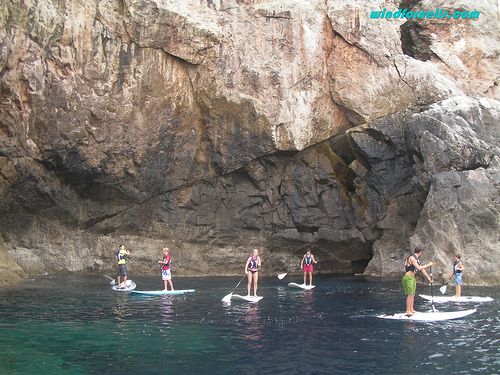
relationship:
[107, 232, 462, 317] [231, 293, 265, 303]
people on paddle board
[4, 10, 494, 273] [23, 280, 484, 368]
cliff above water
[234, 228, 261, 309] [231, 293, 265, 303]
girl on paddle board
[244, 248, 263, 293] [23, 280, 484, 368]
person in water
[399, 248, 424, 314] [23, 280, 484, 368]
person stands on water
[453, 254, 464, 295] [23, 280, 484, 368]
person stands on water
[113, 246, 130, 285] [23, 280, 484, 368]
person stands on water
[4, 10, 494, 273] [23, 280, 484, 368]
cliff near water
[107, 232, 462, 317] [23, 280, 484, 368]
people standing on water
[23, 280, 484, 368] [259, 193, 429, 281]
water near rock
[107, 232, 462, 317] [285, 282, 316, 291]
people standing on paddle board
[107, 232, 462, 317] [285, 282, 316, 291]
people are standing on paddle board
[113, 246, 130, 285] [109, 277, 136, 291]
person with paddle board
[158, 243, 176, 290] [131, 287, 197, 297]
person with paddle board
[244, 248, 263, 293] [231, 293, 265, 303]
person with paddle board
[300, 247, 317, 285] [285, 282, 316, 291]
person with paddle board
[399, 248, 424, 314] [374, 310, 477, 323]
person with paddle board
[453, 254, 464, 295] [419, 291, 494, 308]
person with paddle board